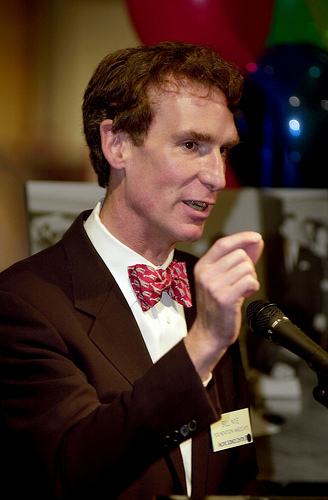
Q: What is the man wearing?
A: A suit and tie.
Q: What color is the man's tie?
A: Red.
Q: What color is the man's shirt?
A: White.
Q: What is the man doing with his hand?
A: Making a gesture.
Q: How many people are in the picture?
A: One.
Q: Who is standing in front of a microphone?
A: A man.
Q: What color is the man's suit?
A: Brown.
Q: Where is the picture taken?
A: At a presentation.